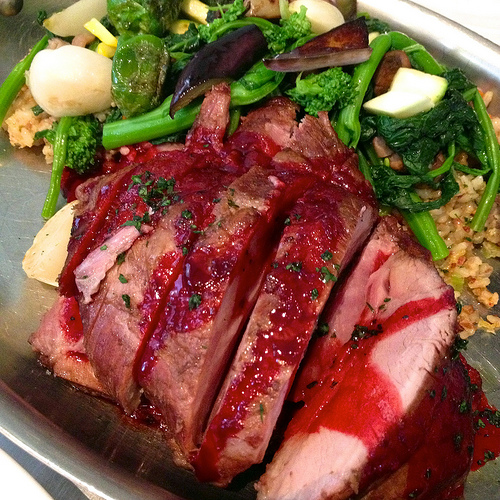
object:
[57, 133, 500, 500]
seasoning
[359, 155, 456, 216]
broccoli leaf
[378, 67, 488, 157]
broccoli leaf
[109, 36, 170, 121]
broccoli leaf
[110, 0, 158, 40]
broccoli leaf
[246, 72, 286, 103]
broccoli leaf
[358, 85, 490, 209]
brocolli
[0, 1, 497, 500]
bowl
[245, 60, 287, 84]
ground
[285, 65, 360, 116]
broccoli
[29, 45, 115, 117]
potatoes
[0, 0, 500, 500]
food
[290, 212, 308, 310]
blood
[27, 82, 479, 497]
meat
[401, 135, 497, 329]
rice plate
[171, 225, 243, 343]
sauce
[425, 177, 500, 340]
rice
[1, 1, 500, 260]
vegetables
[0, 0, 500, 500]
plate